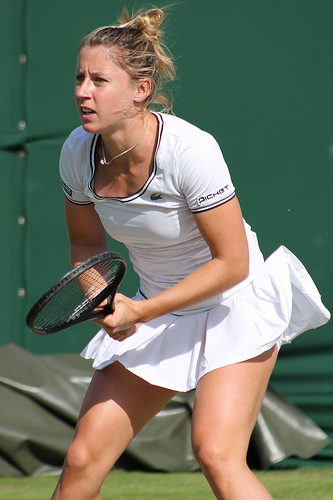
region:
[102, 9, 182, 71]
blond hair in movement.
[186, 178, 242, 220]
A logo that says pichot on it.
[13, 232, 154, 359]
tennis racket and to hands on it.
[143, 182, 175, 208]
An alligator on a white shirt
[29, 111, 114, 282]
Shade on her right arm.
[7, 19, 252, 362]
Girl playing tennis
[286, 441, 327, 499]
Green floor and tarp.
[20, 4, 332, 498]
a woman playing tennis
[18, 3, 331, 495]
a woman holding a tennis racket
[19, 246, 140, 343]
a tennis racket the woman is holding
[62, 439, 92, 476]
a knee of the woman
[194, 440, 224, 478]
a woman's knee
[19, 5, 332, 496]
a woman wearing white shirt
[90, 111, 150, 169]
a necklace the woman is wearing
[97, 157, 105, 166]
a pendant on necklace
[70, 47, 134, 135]
a facial expression of the woman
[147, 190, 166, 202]
a logo on the woman's shirt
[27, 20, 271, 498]
this is a tennis player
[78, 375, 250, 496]
these are the legs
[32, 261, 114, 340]
this is a racket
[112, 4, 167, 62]
the hair is long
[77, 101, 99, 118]
the mouth is open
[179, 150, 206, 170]
the shirt is white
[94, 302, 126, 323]
she's holding the racket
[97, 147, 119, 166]
she's wearing a necklace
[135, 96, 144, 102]
she's wearing earrings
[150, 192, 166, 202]
the logo is green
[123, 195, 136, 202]
the line is maroon